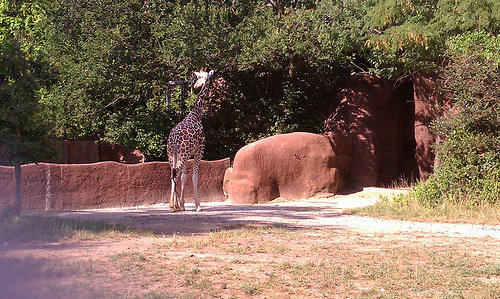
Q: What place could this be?
A: It is a forest.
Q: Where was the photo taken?
A: It was taken at the forest.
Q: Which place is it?
A: It is a forest.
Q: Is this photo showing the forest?
A: Yes, it is showing the forest.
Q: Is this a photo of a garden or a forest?
A: It is showing a forest.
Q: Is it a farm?
A: No, it is a forest.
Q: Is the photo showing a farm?
A: No, the picture is showing a forest.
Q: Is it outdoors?
A: Yes, it is outdoors.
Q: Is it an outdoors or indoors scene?
A: It is outdoors.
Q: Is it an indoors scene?
A: No, it is outdoors.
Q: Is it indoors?
A: No, it is outdoors.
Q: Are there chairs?
A: No, there are no chairs.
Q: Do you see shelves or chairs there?
A: No, there are no chairs or shelves.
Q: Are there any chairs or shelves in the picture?
A: No, there are no chairs or shelves.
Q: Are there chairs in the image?
A: No, there are no chairs.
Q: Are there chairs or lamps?
A: No, there are no chairs or lamps.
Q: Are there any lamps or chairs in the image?
A: No, there are no chairs or lamps.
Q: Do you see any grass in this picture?
A: Yes, there is grass.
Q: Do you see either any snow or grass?
A: Yes, there is grass.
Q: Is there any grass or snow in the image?
A: Yes, there is grass.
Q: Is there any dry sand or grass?
A: Yes, there is dry grass.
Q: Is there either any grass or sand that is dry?
A: Yes, the grass is dry.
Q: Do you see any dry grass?
A: Yes, there is dry grass.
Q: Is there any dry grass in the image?
A: Yes, there is dry grass.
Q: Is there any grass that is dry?
A: Yes, there is grass that is dry.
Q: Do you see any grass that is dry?
A: Yes, there is grass that is dry.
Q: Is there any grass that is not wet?
A: Yes, there is dry grass.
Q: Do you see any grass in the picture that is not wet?
A: Yes, there is dry grass.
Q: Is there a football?
A: No, there are no footballs.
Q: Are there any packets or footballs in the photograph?
A: No, there are no footballs or packets.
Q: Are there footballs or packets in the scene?
A: No, there are no footballs or packets.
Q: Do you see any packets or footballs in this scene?
A: No, there are no footballs or packets.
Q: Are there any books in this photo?
A: No, there are no books.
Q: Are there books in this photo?
A: No, there are no books.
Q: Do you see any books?
A: No, there are no books.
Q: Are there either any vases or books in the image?
A: No, there are no books or vases.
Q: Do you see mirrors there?
A: No, there are no mirrors.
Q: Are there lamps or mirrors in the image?
A: No, there are no mirrors or lamps.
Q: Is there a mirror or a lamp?
A: No, there are no mirrors or lamps.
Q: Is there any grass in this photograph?
A: Yes, there is grass.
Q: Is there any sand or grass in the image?
A: Yes, there is grass.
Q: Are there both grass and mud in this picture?
A: No, there is grass but no mud.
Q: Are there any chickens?
A: No, there are no chickens.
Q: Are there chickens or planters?
A: No, there are no chickens or planters.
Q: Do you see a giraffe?
A: Yes, there is a giraffe.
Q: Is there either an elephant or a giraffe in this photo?
A: Yes, there is a giraffe.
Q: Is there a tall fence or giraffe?
A: Yes, there is a tall giraffe.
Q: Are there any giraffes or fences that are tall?
A: Yes, the giraffe is tall.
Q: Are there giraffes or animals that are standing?
A: Yes, the giraffe is standing.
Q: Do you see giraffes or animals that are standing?
A: Yes, the giraffe is standing.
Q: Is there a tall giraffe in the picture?
A: Yes, there is a tall giraffe.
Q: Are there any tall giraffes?
A: Yes, there is a tall giraffe.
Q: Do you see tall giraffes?
A: Yes, there is a tall giraffe.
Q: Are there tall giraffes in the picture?
A: Yes, there is a tall giraffe.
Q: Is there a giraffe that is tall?
A: Yes, there is a giraffe that is tall.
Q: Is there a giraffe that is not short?
A: Yes, there is a tall giraffe.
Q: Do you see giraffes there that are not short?
A: Yes, there is a tall giraffe.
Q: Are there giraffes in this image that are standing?
A: Yes, there is a giraffe that is standing.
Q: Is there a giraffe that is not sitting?
A: Yes, there is a giraffe that is standing.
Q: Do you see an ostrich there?
A: No, there are no ostriches.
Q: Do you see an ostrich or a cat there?
A: No, there are no ostriches or cats.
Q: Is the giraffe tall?
A: Yes, the giraffe is tall.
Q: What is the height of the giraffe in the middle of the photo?
A: The giraffe is tall.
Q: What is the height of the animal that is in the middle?
A: The giraffe is tall.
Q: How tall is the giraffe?
A: The giraffe is tall.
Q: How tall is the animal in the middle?
A: The giraffe is tall.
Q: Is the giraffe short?
A: No, the giraffe is tall.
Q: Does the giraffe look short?
A: No, the giraffe is tall.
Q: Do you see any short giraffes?
A: No, there is a giraffe but it is tall.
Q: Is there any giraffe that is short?
A: No, there is a giraffe but it is tall.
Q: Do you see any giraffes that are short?
A: No, there is a giraffe but it is tall.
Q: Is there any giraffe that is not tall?
A: No, there is a giraffe but it is tall.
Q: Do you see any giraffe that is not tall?
A: No, there is a giraffe but it is tall.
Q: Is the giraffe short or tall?
A: The giraffe is tall.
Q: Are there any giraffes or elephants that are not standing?
A: No, there is a giraffe but it is standing.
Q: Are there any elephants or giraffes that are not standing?
A: No, there is a giraffe but it is standing.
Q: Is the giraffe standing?
A: Yes, the giraffe is standing.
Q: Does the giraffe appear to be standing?
A: Yes, the giraffe is standing.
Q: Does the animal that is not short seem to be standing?
A: Yes, the giraffe is standing.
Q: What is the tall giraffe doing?
A: The giraffe is standing.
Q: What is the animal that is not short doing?
A: The giraffe is standing.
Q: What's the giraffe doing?
A: The giraffe is standing.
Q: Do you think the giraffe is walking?
A: No, the giraffe is standing.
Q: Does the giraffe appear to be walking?
A: No, the giraffe is standing.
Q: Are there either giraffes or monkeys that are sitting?
A: No, there is a giraffe but it is standing.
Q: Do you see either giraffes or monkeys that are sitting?
A: No, there is a giraffe but it is standing.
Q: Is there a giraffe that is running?
A: No, there is a giraffe but it is standing.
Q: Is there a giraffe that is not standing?
A: No, there is a giraffe but it is standing.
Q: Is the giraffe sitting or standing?
A: The giraffe is standing.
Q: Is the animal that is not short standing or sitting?
A: The giraffe is standing.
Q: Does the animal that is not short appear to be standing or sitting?
A: The giraffe is standing.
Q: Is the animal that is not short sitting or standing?
A: The giraffe is standing.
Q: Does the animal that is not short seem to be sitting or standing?
A: The giraffe is standing.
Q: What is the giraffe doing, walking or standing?
A: The giraffe is standing.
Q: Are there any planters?
A: No, there are no planters.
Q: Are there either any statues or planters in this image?
A: No, there are no planters or statues.